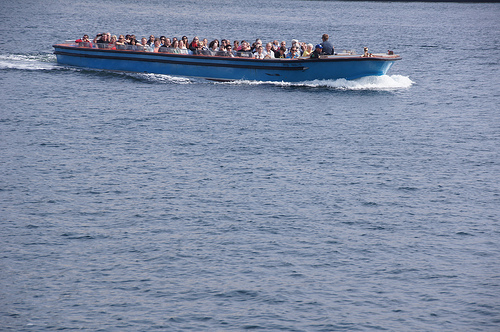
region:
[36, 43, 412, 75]
this is a speed boat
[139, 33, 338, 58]
people are in the boat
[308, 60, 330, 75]
the boat is blue in color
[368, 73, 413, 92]
the water is splashing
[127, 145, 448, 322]
the water is blue in color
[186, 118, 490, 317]
the water is calm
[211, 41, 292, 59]
the people are sitted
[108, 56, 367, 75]
the boat is long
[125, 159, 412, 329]
the waves are small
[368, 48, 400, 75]
the front is sharp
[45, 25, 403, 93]
long white boat filled with people floating on body of water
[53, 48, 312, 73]
thin dark blue line on side of boat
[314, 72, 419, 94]
white froth on top of water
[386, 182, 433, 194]
ripple in body of water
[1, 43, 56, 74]
stream of white water waves behind boat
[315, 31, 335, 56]
person at front of boat wearing a hat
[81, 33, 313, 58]
group of people sitting in blue boat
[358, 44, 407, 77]
two people sitting at front of boat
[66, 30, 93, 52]
person sitting in very back of boat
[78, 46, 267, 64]
short glass shield at lip edge of boat on sides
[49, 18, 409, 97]
long blue boat on the water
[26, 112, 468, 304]
pretty calm water with only very small ripples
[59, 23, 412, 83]
a big group of people sitting on a boat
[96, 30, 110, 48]
person taking a picture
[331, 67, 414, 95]
wave made my the boat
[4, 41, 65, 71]
wake coming off the back of the boat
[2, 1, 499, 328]
blue water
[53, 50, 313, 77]
thin black line on the blue paint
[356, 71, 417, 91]
white wave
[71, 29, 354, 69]
humans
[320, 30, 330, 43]
the head of a man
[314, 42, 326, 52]
a blue baseball cap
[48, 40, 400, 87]
a long blue boat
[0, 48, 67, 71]
the wake of a boat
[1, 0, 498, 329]
a large blue body of water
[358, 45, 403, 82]
the bow of the boat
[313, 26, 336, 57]
a person on the boat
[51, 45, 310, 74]
a black line on the boat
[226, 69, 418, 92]
white water around the boat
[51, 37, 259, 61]
a small glass guard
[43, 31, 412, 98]
a long boat with lots of people.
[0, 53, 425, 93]
Foam created by a long boat.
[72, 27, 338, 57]
a crowd of people inside of a boat.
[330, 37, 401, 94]
the front end of a boat.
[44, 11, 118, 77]
the back end of a boat.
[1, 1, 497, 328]
a large boat floating on a body of water.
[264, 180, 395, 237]
a section of small waves in the water.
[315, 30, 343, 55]
a man standing at the front of a boat.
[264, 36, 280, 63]
a woman in a white shirt.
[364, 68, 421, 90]
choppy water.